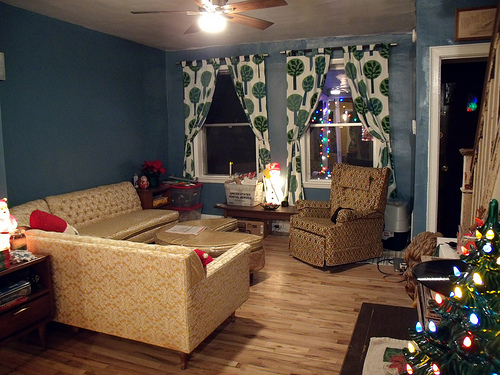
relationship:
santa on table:
[0, 193, 16, 267] [1, 256, 54, 352]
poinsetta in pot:
[151, 160, 166, 185] [149, 178, 159, 186]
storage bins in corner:
[170, 181, 200, 206] [161, 104, 175, 161]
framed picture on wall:
[454, 7, 495, 42] [424, 14, 452, 42]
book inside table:
[2, 278, 35, 299] [1, 256, 54, 352]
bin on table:
[223, 183, 261, 204] [1, 256, 54, 352]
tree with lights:
[450, 201, 499, 370] [455, 287, 463, 299]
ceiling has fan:
[86, 3, 119, 28] [229, 0, 288, 31]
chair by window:
[292, 164, 386, 265] [311, 122, 364, 151]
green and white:
[288, 59, 304, 71] [297, 73, 305, 81]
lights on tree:
[455, 287, 463, 299] [450, 201, 499, 370]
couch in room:
[83, 239, 215, 338] [4, 1, 498, 337]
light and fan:
[199, 15, 228, 35] [229, 0, 288, 31]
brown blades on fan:
[246, 3, 269, 9] [229, 0, 288, 31]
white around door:
[440, 45, 482, 55] [428, 48, 461, 230]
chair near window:
[292, 164, 386, 265] [311, 122, 364, 151]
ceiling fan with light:
[86, 3, 119, 28] [199, 15, 228, 35]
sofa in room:
[71, 184, 138, 230] [4, 1, 498, 337]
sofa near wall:
[71, 184, 138, 230] [424, 14, 452, 42]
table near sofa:
[1, 256, 54, 352] [71, 184, 138, 230]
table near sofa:
[218, 210, 288, 217] [71, 184, 138, 230]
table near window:
[1, 256, 54, 352] [311, 122, 364, 151]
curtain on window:
[185, 56, 266, 152] [311, 122, 364, 151]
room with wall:
[4, 1, 498, 337] [424, 14, 452, 42]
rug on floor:
[367, 308, 396, 327] [272, 334, 316, 369]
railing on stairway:
[475, 156, 496, 194] [480, 94, 498, 139]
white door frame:
[440, 45, 482, 55] [430, 49, 441, 220]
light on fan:
[199, 15, 228, 35] [229, 0, 288, 31]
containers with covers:
[182, 182, 197, 219] [171, 183, 190, 189]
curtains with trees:
[186, 48, 396, 158] [240, 57, 264, 99]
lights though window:
[315, 133, 332, 166] [311, 122, 364, 151]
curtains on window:
[186, 48, 396, 158] [311, 122, 364, 151]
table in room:
[1, 256, 54, 352] [4, 1, 498, 337]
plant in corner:
[151, 160, 166, 185] [161, 104, 175, 161]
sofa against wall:
[71, 184, 138, 230] [424, 14, 452, 42]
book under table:
[2, 278, 35, 299] [1, 256, 54, 352]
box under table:
[243, 222, 271, 234] [218, 210, 288, 217]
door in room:
[428, 48, 461, 230] [4, 1, 498, 337]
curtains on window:
[284, 42, 393, 208] [197, 70, 253, 174]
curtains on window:
[182, 53, 268, 183] [306, 66, 375, 178]